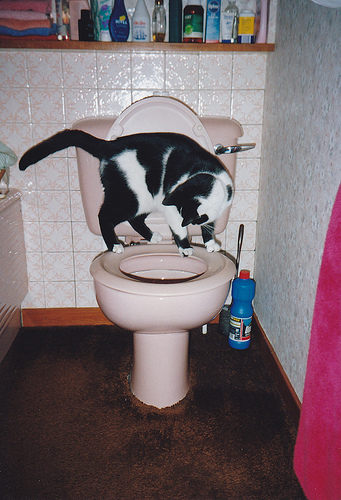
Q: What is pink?
A: The toilet.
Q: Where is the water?
A: In the toilet.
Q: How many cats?
A: One.